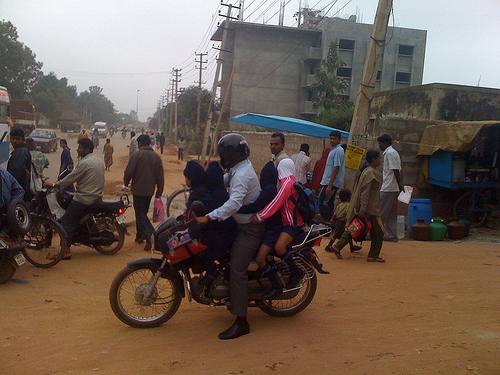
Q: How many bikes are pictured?
A: 4.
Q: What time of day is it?
A: Day time.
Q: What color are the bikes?
A: Red and black.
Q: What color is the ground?
A: Orange.